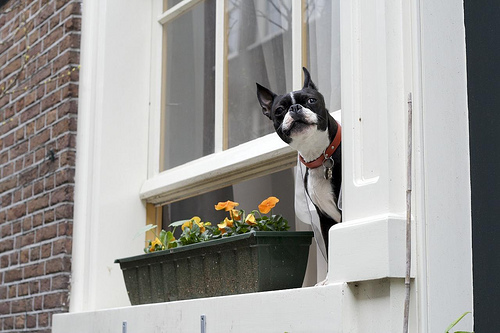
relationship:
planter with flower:
[113, 228, 315, 305] [258, 193, 280, 215]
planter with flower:
[113, 228, 315, 305] [215, 197, 237, 209]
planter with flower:
[113, 228, 315, 305] [178, 215, 203, 227]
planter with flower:
[113, 228, 315, 305] [145, 234, 164, 251]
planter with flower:
[113, 228, 315, 305] [214, 222, 230, 231]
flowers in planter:
[142, 194, 291, 256] [113, 228, 315, 305]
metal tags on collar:
[316, 160, 348, 187] [292, 142, 357, 179]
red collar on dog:
[299, 123, 344, 171] [250, 68, 339, 253]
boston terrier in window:
[253, 66, 342, 286] [135, 159, 332, 273]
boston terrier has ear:
[253, 66, 342, 286] [253, 80, 278, 120]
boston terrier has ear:
[253, 66, 342, 286] [301, 65, 318, 93]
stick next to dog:
[400, 89, 420, 331] [251, 64, 344, 288]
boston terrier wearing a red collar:
[253, 66, 342, 286] [299, 123, 344, 171]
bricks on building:
[13, 62, 67, 165] [5, 7, 496, 320]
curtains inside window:
[230, 4, 343, 286] [146, 2, 347, 287]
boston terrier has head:
[246, 66, 348, 188] [252, 79, 336, 160]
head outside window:
[252, 79, 336, 160] [143, 2, 261, 164]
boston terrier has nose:
[253, 66, 342, 286] [284, 100, 300, 117]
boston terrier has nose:
[253, 66, 342, 286] [290, 106, 304, 116]